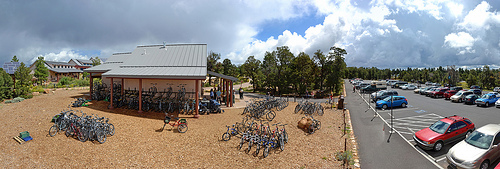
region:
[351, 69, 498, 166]
cars in a parking lot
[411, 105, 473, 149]
red car in a parking lot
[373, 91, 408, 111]
blue car in a parking lot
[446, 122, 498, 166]
gray car in a parking lot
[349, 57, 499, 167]
trees behind a parking lot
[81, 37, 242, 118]
roof is color gray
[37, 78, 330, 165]
bikes in front a building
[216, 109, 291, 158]
a row of bikes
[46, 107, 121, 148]
a row of bikes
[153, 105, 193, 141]
bike is parking on the ground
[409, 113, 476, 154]
a red car in a parking lot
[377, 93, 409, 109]
a blue car in a parking lot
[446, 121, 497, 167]
a silver car in a parking lot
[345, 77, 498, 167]
a parking lot full of cars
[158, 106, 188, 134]
a motorbike in front of a house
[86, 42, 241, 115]
a house surrounded with bikes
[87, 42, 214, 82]
a metal roof on a house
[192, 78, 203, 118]
a support post on a house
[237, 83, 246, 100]
a person standing in front of a house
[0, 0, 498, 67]
a cloudy sky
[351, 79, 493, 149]
lot with vehicles in it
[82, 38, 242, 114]
shelter area on earth space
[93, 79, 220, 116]
bikes around the shelter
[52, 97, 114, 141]
bikes on the earth space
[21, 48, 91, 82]
building behind shelter area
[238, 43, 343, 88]
trees near the structure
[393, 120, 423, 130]
marks on the lot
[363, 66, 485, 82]
trees in the lot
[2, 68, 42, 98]
trees near the building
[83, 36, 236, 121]
square building surrounded by bicycles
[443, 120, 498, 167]
white car parked in parking lot near building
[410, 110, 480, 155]
red car parked in concrete gray parking lot near building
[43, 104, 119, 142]
group of metal bicycles parked near building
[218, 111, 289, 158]
group of metal bicycles parked near building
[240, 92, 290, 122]
group of metal bicycles parked near building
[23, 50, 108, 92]
building near building surrounded by bicycles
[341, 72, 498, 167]
gray paved concrete parking lot near building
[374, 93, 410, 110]
blue car parked in parking lot near building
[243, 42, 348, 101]
group of green trees near building and parking lot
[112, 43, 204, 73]
this is the roof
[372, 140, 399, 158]
this is the road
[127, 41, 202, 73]
the roof is grey in color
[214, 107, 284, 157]
these are the bikes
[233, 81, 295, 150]
the bikes are parked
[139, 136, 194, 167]
this is the ground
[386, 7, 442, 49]
these are the clouds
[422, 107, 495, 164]
the cars are parked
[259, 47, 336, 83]
these are the trees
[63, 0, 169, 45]
the clouds are dark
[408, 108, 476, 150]
car is red in color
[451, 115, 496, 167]
car is gold in color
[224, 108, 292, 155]
bikes are on a rack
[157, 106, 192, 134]
bike is red in color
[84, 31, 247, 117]
hut has many bikes under it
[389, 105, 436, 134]
white lines on parking lot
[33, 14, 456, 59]
the sky is very cloudy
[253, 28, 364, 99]
leaves of the trees are green